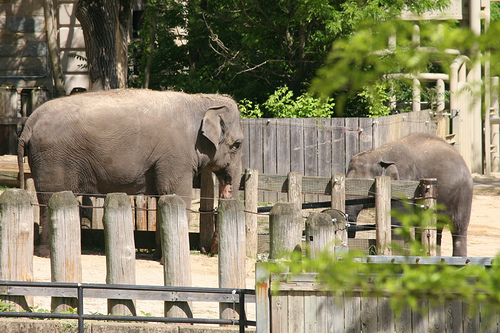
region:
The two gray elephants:
[16, 91, 476, 268]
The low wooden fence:
[1, 114, 498, 331]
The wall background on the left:
[0, 0, 150, 155]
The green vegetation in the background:
[132, 0, 499, 117]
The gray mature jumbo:
[17, 93, 244, 246]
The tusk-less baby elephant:
[344, 130, 475, 260]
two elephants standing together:
[21, 29, 488, 279]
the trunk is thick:
[205, 151, 251, 246]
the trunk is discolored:
[202, 165, 237, 257]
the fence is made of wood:
[249, 110, 356, 180]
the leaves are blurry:
[281, 193, 486, 318]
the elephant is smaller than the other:
[320, 130, 480, 255]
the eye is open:
[215, 126, 255, 171]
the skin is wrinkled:
[50, 124, 120, 186]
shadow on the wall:
[0, 12, 68, 84]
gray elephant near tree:
[12, 83, 249, 260]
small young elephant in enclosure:
[329, 130, 477, 272]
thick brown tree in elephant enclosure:
[65, 0, 142, 240]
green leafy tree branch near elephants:
[251, 183, 498, 331]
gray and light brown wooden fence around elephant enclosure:
[246, 250, 497, 331]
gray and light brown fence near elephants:
[0, 166, 441, 270]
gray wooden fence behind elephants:
[121, 105, 454, 220]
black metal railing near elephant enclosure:
[1, 275, 269, 331]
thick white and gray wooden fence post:
[154, 190, 195, 331]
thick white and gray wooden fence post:
[43, 186, 84, 331]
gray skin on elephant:
[96, 145, 103, 152]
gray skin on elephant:
[397, 147, 401, 150]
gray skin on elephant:
[191, 96, 203, 105]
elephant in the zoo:
[22, 84, 258, 225]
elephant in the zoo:
[342, 122, 465, 262]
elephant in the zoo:
[25, 80, 248, 239]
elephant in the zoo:
[331, 126, 485, 275]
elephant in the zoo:
[293, 109, 470, 241]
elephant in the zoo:
[331, 128, 478, 263]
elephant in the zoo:
[305, 135, 478, 265]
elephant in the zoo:
[338, 135, 468, 266]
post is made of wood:
[198, 178, 256, 286]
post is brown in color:
[215, 196, 256, 286]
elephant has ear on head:
[191, 106, 238, 156]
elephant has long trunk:
[214, 149, 255, 190]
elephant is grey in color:
[18, 102, 255, 190]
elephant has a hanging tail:
[12, 121, 39, 202]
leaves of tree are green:
[287, 229, 492, 303]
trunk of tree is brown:
[95, 16, 136, 84]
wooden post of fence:
[1, 187, 34, 313]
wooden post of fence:
[47, 188, 81, 313]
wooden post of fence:
[101, 192, 137, 314]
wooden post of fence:
[156, 190, 197, 317]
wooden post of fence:
[217, 194, 241, 318]